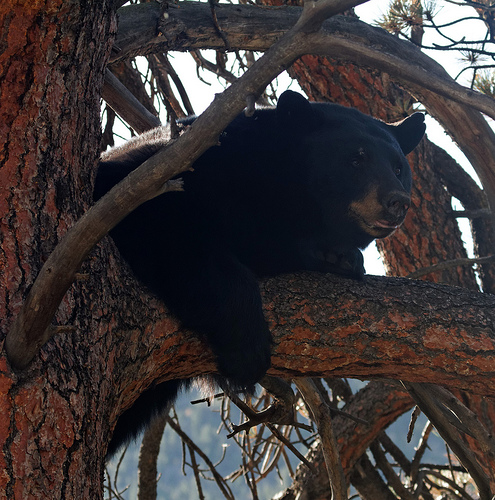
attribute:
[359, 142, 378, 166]
mark — greyish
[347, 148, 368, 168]
eye — big, brown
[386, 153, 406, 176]
eye — big, brown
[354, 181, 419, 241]
mouth — brown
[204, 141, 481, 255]
bear — big, black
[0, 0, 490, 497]
tree — red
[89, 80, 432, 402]
bear — black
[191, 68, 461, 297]
bear — black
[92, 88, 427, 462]
bear — fat, big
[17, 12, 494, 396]
branches — big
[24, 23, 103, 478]
sticks — brown